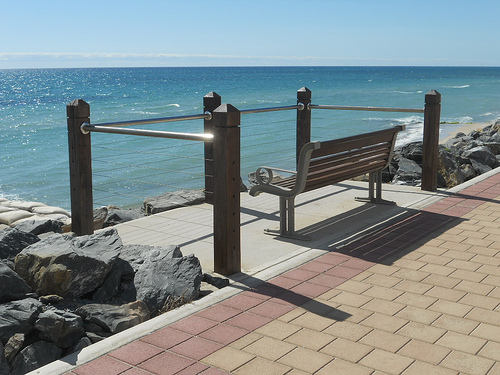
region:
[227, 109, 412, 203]
the bench is empty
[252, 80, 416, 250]
the bench is empty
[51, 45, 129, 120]
the water is blue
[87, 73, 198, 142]
the water is blue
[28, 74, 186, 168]
the water is blue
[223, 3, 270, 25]
this is the sky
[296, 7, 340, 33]
the sky is blue in color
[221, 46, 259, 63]
the sky has clouds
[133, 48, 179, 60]
the clouds are white in color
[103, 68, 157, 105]
this is the water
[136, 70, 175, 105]
the water is blue in color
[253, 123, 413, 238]
this is a bench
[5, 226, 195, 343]
these are some rocks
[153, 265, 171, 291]
the rock is grey in color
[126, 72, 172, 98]
the water has ripples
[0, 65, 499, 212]
the body of water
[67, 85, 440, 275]
the railing around the bench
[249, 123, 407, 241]
the bench near the water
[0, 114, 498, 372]
the large rocks near the water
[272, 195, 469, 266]
the shadow of the bench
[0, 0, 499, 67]
the blue sky above the ocean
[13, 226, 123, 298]
the large rock near the bench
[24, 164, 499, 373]
the walkway behind the bench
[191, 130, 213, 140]
the sun reflecting off of the metal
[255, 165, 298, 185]
the arm rest on the bench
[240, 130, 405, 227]
a bench by the water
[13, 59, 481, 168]
a blue body of water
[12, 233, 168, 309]
rocks around the water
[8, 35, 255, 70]
clouds in the sky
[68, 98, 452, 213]
a fence around the bench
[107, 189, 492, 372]
bricks on the ground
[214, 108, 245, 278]
a post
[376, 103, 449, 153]
waves in the water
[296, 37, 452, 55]
the clear blue sky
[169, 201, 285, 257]
the cement under the bench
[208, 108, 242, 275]
pole on the concrete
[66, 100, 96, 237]
pole on the concrete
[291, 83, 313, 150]
pole on the concrete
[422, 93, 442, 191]
pole on the concrete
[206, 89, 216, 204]
pole on the concrete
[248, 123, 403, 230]
bench on the concrete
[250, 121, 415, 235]
bench between poles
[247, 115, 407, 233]
bench facing the water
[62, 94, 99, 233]
pole near the water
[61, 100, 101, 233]
pole near rocks